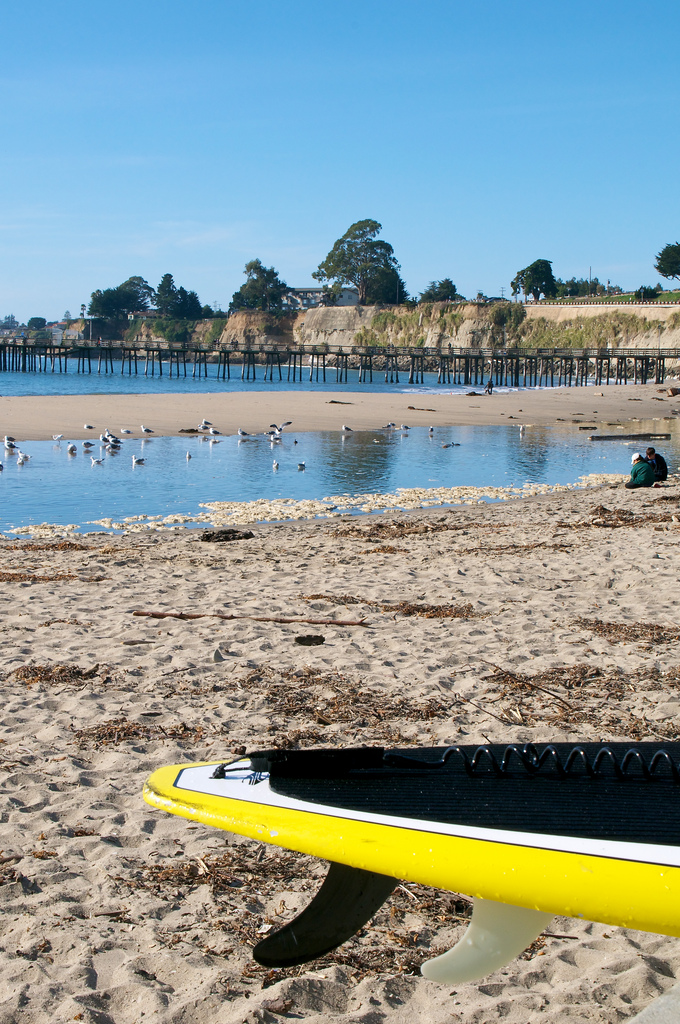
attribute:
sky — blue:
[424, 97, 483, 201]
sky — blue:
[492, 83, 565, 128]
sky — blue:
[495, 137, 561, 196]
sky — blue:
[41, 126, 89, 196]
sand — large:
[410, 630, 498, 686]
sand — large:
[92, 967, 206, 1016]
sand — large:
[488, 586, 575, 656]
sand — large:
[592, 557, 653, 618]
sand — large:
[13, 933, 132, 1013]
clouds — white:
[28, 205, 264, 269]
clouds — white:
[138, 219, 244, 249]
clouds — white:
[172, 215, 247, 252]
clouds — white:
[38, 156, 156, 175]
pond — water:
[0, 425, 677, 536]